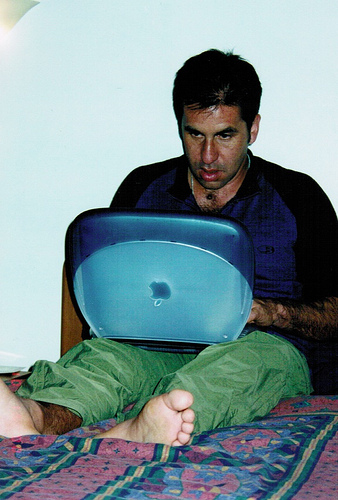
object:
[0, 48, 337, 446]
man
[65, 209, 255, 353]
laptop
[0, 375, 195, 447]
feet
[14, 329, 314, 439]
pants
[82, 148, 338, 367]
shirt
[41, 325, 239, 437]
leg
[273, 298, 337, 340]
arm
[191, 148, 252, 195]
necklace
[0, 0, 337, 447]
wall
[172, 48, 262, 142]
hair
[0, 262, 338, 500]
bed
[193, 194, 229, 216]
chest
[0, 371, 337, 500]
bedspread